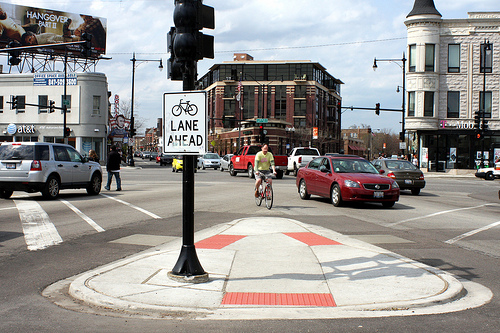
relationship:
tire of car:
[320, 181, 345, 216] [283, 132, 404, 224]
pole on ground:
[156, 72, 219, 258] [128, 253, 244, 321]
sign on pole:
[153, 83, 219, 163] [156, 72, 219, 258]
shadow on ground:
[311, 265, 383, 279] [128, 253, 244, 321]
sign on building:
[153, 83, 219, 163] [237, 47, 320, 121]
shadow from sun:
[311, 265, 383, 279] [360, 31, 391, 53]